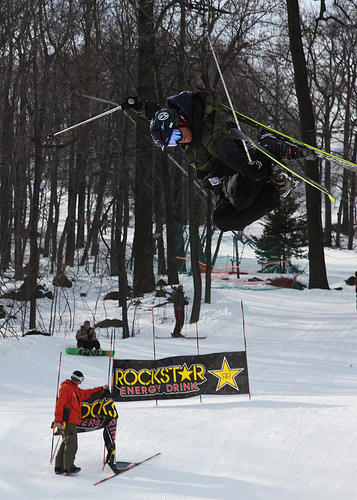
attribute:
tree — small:
[245, 193, 306, 278]